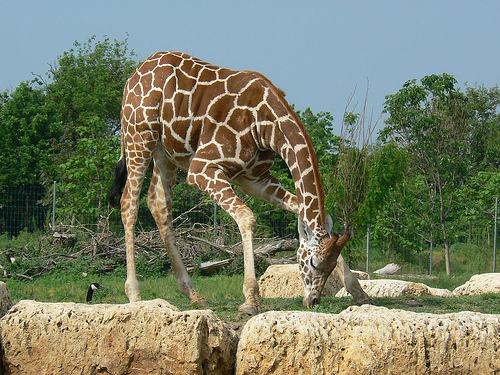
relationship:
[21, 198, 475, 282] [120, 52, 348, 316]
fence behind giraffe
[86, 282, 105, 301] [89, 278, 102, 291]
bird has face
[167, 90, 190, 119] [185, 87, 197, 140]
patches are on line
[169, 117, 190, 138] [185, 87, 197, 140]
patches are on line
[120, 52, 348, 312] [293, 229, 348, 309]
giraffe has head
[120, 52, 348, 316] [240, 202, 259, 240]
giraffe has knee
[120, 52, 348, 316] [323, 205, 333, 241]
giraffe has knee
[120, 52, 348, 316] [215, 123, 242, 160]
giraffe has spot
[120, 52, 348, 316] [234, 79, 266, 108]
giraffe has spot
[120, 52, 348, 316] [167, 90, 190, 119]
giraffe has patches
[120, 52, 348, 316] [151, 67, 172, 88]
giraffe has spot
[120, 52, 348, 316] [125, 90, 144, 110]
giraffe has spot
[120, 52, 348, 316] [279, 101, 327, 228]
giraffe has neck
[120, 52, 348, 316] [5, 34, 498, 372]
giraffe in wildlife park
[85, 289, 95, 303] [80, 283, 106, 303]
neck of bird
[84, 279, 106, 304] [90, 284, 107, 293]
bird has face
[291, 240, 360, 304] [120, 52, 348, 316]
head of giraffe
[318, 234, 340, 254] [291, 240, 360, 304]
horn on head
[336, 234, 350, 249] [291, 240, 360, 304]
horn on head